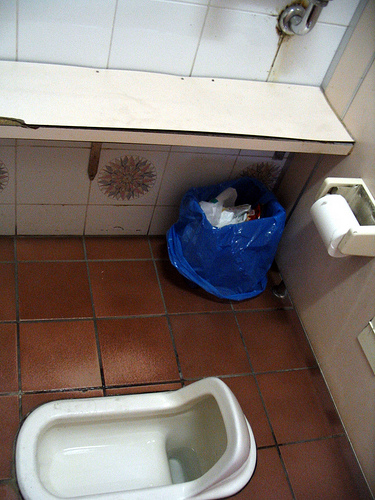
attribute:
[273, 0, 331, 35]
pipe — corrosion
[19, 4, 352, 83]
tile — white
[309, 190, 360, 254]
toilet paper — roll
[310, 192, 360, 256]
roll — toilet paper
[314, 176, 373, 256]
holder — toilet paper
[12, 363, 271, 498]
urinal — cleaner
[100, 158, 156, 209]
tile — decorative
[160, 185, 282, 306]
garbage bag — blue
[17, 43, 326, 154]
counter top — white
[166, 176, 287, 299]
bag — blue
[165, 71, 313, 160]
shelf — small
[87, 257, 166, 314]
tile — red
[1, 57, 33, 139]
shelf — broken, coming apart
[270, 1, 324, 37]
plumbing — silver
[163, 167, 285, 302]
trashbag — blue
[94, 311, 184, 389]
tile — red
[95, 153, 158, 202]
design — round, circled